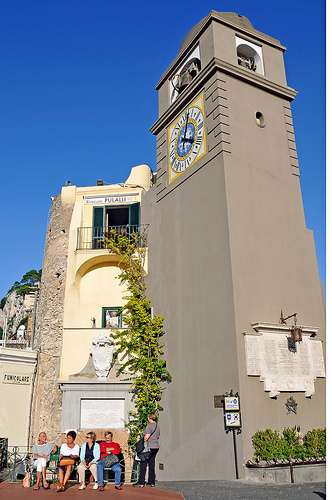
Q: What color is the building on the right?
A: Gray.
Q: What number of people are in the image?
A: Five.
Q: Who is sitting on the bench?
A: The people.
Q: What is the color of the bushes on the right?
A: Green.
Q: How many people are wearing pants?
A: Three.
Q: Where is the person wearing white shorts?
A: On the left.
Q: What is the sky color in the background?
A: Blue.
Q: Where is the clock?
A: On the building.